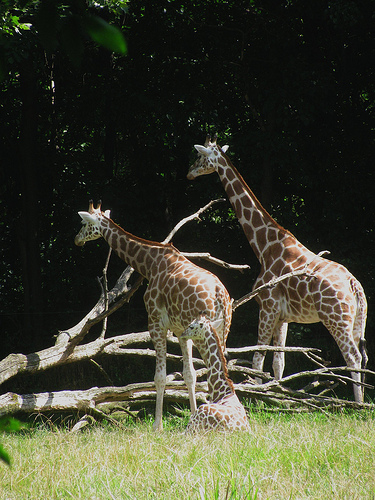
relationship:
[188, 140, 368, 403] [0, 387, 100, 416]
giraffe standing by tree trunk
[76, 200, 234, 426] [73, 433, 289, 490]
giraffe sitting in grass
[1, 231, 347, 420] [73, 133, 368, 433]
logs near giraffes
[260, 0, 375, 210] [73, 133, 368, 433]
tree behind giraffes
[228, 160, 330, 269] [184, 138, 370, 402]
brown mane on giraffe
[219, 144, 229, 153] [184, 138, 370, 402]
ear on giraffe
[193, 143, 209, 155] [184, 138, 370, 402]
ear on giraffe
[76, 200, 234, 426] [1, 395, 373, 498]
giraffe in field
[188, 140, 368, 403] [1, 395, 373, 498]
giraffe in field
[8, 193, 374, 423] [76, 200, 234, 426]
tree near giraffe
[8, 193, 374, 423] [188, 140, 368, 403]
tree near giraffe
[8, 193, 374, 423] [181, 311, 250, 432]
tree near giraffe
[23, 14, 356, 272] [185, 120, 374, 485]
green leaves behind giraffes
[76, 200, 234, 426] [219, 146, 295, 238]
giraffe has brown mane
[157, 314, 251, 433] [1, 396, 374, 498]
giraffe in grass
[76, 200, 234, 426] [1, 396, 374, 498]
giraffe in grass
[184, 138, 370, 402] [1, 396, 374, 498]
giraffe in grass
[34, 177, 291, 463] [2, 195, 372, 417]
giraffe standing before logs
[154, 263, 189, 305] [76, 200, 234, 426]
spots on giraffe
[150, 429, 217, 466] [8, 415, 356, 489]
grass in field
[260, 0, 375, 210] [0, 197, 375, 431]
tree before branches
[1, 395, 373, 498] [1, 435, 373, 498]
field of grass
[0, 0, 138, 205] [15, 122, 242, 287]
green leaves on trees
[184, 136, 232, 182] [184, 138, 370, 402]
head of giraffe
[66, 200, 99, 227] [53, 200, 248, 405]
ear of giraffe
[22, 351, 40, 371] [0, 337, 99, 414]
shadow on tree trunk